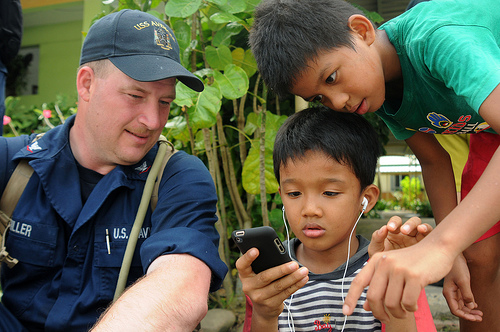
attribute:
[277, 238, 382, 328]
shirt — striped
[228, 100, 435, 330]
boy — older 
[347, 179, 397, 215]
earbuds — white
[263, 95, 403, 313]
boy — young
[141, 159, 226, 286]
sleeve — sailor's  , rolled up